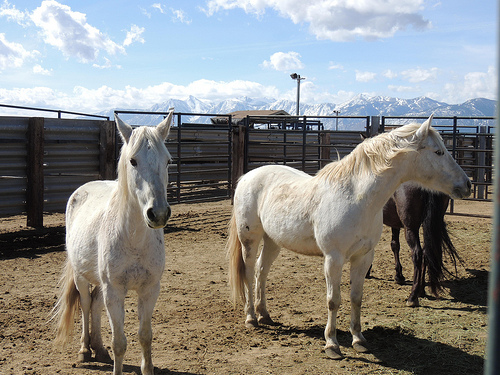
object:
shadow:
[257, 319, 485, 374]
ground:
[1, 176, 500, 374]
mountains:
[71, 93, 498, 134]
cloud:
[30, 0, 128, 62]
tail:
[415, 185, 467, 298]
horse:
[350, 124, 470, 305]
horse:
[45, 110, 175, 373]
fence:
[0, 103, 500, 228]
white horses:
[225, 114, 473, 358]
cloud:
[201, 0, 436, 43]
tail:
[222, 202, 252, 310]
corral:
[0, 106, 499, 374]